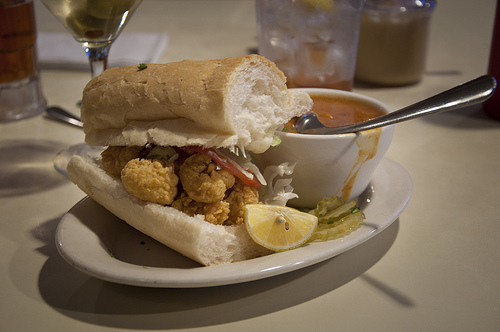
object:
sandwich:
[66, 54, 313, 266]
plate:
[55, 153, 413, 289]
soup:
[286, 92, 383, 130]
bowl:
[247, 86, 397, 208]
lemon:
[242, 201, 318, 251]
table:
[2, 67, 498, 327]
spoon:
[296, 72, 498, 136]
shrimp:
[121, 157, 178, 204]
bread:
[81, 54, 315, 153]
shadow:
[36, 216, 414, 331]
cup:
[252, 0, 363, 95]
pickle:
[310, 195, 363, 242]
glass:
[38, 0, 146, 180]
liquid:
[0, 0, 38, 82]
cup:
[1, 0, 50, 125]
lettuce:
[231, 149, 299, 203]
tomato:
[197, 144, 260, 189]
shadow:
[0, 137, 71, 197]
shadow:
[422, 82, 499, 128]